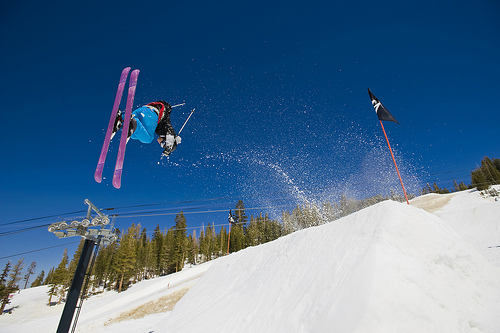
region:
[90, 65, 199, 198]
Skiier doing a trick in the air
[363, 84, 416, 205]
Black and red flag on hill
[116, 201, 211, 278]
Trees on snowy hill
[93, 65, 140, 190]
Pair of purple skiis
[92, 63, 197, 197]
Person holding ski poles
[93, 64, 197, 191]
Person wearing snow gear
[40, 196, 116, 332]
Power line on hill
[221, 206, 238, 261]
Black and red flag pole in background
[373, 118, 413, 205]
Red pole holding flag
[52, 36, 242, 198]
the skier jumped in the air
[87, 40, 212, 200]
the person is in the air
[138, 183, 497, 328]
this is a ramp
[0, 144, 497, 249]
the wires on a ski lift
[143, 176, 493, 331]
this is a ramp made of snow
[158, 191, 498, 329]
a snow ramp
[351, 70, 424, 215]
the flag post is orange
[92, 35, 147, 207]
the skis are purple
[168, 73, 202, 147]
the ski poles are white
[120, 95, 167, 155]
his pants are blue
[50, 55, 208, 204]
skier in the air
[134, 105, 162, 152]
pants on the skier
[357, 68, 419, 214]
flag on the slope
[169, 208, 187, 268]
pine tree on slope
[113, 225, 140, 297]
pine tree on slope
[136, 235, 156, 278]
pine tree on slope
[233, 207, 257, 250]
pine tree on slope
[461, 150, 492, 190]
pine tree on slope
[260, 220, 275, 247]
pine tree on slope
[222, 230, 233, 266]
pine tree on slope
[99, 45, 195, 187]
Man in the sky on the skiis.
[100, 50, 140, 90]
The top portion of purple skies.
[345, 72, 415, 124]
A black flag on a red pole.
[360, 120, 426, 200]
A long red pole.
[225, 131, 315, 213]
A trail of falling snow.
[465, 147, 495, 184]
Some trees in the distance.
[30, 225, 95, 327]
A long black pole.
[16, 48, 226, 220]
A skier getting some air time.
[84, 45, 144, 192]
a set of skis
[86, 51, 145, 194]
the skis are pink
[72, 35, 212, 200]
person doing a trick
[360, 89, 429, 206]
flag on a pole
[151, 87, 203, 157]
a set of ski poles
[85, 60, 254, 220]
the person is jumping skis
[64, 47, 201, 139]
the person is air born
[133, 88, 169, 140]
the pants are blue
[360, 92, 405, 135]
the flag is black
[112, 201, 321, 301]
the background has a forest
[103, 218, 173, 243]
the tree are evergreens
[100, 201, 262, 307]
the trees are yellow and green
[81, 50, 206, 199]
The skier in the air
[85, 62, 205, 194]
A skier in the air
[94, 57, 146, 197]
The pink skis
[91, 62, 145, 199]
A set of pink skis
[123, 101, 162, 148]
The blue pants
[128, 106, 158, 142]
A set of blue pants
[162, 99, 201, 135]
The ski poles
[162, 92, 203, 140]
A set of silver ski poles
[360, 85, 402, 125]
The black flag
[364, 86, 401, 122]
A black flag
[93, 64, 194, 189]
someone wearing a pair of skis